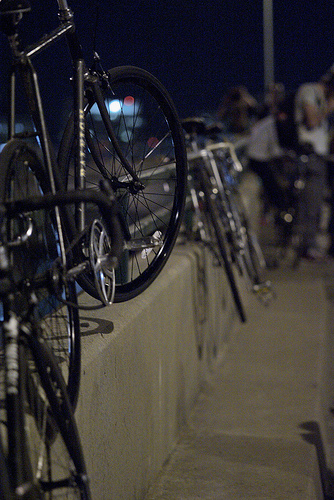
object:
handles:
[0, 180, 124, 246]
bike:
[0, 221, 102, 494]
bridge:
[0, 109, 334, 500]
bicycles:
[0, 0, 187, 418]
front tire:
[50, 63, 187, 306]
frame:
[3, 18, 84, 153]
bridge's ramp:
[0, 103, 298, 362]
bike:
[172, 111, 268, 338]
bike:
[183, 109, 284, 323]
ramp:
[41, 134, 264, 304]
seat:
[175, 109, 209, 138]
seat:
[202, 120, 224, 139]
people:
[248, 63, 330, 257]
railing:
[108, 131, 231, 279]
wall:
[65, 253, 232, 500]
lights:
[109, 98, 123, 113]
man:
[295, 64, 334, 262]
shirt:
[291, 80, 329, 165]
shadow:
[297, 417, 334, 500]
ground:
[140, 259, 333, 500]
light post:
[261, 0, 277, 99]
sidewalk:
[152, 162, 329, 499]